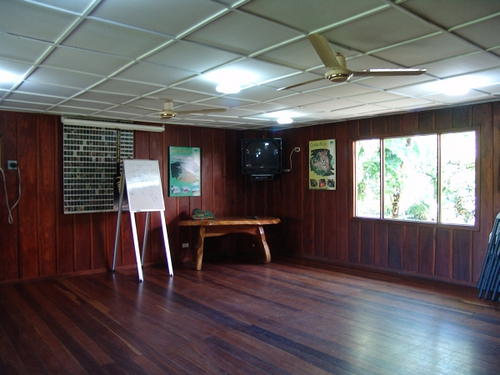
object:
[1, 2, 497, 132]
ceiling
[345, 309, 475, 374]
reflection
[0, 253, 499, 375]
floor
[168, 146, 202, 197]
art frame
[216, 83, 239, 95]
light fixture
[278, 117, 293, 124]
light fixture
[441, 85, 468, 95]
light fixture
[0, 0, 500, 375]
room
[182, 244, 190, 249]
plug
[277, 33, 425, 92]
ceiling fan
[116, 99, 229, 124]
ceiling fan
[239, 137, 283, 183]
television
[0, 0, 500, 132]
roof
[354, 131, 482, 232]
window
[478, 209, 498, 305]
chairs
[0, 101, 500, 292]
wall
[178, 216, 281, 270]
table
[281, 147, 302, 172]
wire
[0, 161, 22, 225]
wire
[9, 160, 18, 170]
socket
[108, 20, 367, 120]
design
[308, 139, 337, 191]
painting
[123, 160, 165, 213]
board